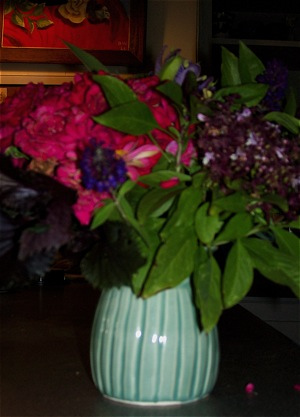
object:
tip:
[139, 293, 150, 300]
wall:
[139, 0, 199, 86]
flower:
[0, 170, 70, 279]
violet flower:
[174, 63, 208, 87]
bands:
[100, 286, 123, 396]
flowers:
[3, 40, 300, 299]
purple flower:
[200, 94, 299, 212]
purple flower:
[249, 59, 288, 114]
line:
[158, 290, 181, 404]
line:
[174, 286, 196, 401]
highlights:
[106, 309, 193, 375]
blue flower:
[254, 57, 290, 108]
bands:
[112, 287, 133, 399]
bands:
[92, 283, 112, 397]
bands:
[122, 288, 145, 401]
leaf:
[103, 189, 300, 332]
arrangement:
[0, 63, 300, 392]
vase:
[91, 266, 215, 415]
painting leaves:
[11, 17, 55, 31]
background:
[2, 0, 300, 73]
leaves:
[59, 38, 296, 330]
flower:
[2, 74, 193, 221]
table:
[0, 291, 300, 417]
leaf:
[191, 246, 225, 328]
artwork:
[0, 1, 147, 77]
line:
[187, 290, 209, 400]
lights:
[132, 322, 164, 350]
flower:
[79, 145, 127, 190]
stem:
[111, 187, 145, 255]